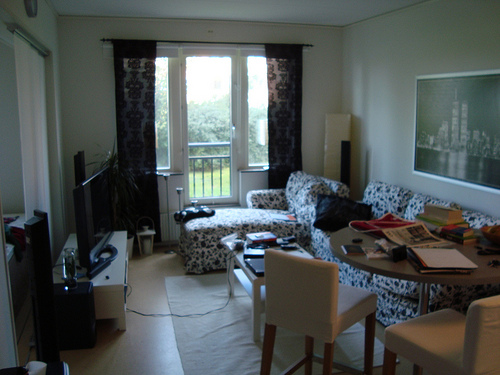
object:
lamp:
[323, 107, 350, 187]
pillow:
[312, 194, 371, 233]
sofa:
[314, 157, 500, 339]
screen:
[76, 165, 116, 266]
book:
[245, 231, 277, 244]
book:
[243, 240, 265, 258]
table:
[224, 237, 320, 342]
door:
[186, 50, 238, 206]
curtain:
[12, 34, 52, 225]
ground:
[431, 142, 456, 177]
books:
[424, 205, 461, 225]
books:
[447, 234, 479, 246]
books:
[382, 221, 446, 248]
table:
[328, 219, 500, 374]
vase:
[63, 253, 75, 277]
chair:
[180, 171, 350, 273]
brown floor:
[41, 243, 180, 373]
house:
[2, 0, 497, 373]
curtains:
[113, 38, 163, 243]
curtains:
[264, 43, 302, 190]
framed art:
[412, 70, 500, 195]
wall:
[340, 0, 499, 212]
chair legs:
[259, 249, 378, 375]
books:
[411, 247, 478, 270]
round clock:
[24, 0, 38, 16]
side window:
[0, 20, 28, 260]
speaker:
[24, 209, 64, 374]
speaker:
[70, 145, 87, 186]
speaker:
[339, 137, 351, 188]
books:
[442, 225, 473, 238]